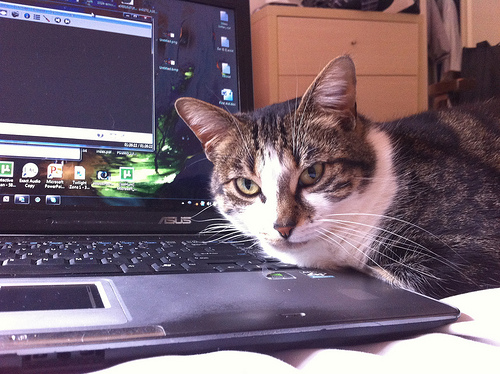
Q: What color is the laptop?
A: Black.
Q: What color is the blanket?
A: White.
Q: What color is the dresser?
A: Brown.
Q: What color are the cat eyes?
A: Yellow.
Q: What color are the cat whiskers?
A: White.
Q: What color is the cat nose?
A: Pink.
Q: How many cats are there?
A: One.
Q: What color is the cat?
A: Gray.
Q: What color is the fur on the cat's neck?
A: White.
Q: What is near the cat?
A: Computer.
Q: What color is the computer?
A: Black.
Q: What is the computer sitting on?
A: Table.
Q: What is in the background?
A: Cabinet.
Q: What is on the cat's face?
A: Whiskers.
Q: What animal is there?
A: Cat.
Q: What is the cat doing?
A: Laying down.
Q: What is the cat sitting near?
A: Laptop.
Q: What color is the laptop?
A: Black.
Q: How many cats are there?
A: 1.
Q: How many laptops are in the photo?
A: One.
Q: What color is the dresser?
A: Brown.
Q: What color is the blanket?
A: WHite.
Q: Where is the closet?
A: Behind the dresser.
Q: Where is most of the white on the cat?
A: Chin and neck.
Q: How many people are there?
A: 1.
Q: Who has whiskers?
A: Cat.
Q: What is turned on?
A: Laptop.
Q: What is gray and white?
A: The cat.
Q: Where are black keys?
A: On laptop.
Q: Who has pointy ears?
A: A cat.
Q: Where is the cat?
A: On a bed.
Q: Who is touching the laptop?
A: Cat.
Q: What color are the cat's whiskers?
A: White.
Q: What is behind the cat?
A: Chest of drawers.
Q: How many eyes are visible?
A: Two.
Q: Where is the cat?
A: Right of the laptop.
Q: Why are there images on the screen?
A: Computer is on.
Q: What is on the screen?
A: Open window.